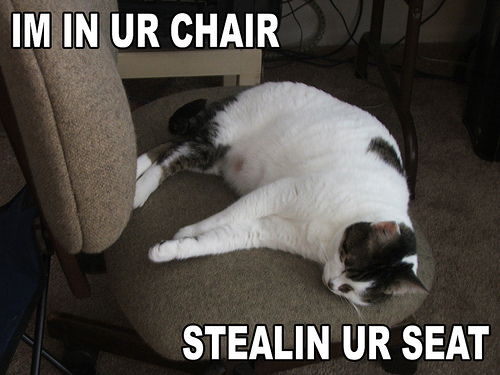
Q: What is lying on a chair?
A: A cat.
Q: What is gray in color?
A: The chair.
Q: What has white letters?
A: The words on the picture.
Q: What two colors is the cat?
A: Brown and white.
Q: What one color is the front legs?
A: White.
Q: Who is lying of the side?
A: The cat.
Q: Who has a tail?
A: The cat.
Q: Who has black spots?
A: The cat.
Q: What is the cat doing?
A: Sleeping.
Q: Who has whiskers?
A: The cat.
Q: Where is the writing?
A: In the corners of the picture.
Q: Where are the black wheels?
A: On the chair.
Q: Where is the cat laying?
A: On the chair.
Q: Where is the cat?
A: On the chair.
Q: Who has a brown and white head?
A: The cat.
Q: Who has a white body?
A: The cat.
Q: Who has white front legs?
A: The cat.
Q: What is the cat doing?
A: Sleeping on the chair.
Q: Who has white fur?
A: The cat.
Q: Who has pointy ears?
A: The cat.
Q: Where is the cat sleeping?
A: On the chair.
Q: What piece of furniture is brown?
A: The chair.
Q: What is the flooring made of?
A: Carpet.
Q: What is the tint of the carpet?
A: Beige.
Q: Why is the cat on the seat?
A: For comfort.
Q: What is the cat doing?
A: Sleeping.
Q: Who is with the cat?
A: No one.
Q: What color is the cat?
A: White and black.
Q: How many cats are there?
A: 1.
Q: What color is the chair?
A: Grey.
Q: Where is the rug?
A: On the floor.